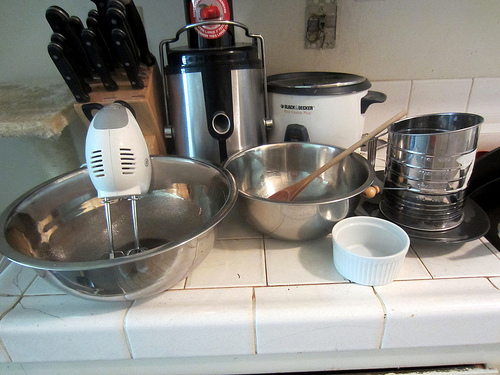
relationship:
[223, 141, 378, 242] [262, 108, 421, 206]
bowl with spoon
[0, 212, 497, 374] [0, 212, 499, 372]
tiles on counter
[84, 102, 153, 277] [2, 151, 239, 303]
hand mixer in bowl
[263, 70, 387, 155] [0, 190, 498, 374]
crock pot on counter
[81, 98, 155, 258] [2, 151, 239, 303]
hand mixer in bowl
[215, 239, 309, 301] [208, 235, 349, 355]
grout between tiles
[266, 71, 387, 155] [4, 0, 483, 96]
crock pot against wall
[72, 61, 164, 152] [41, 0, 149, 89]
brick with knives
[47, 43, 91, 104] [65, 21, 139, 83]
knife with handles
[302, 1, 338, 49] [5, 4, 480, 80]
socket on wall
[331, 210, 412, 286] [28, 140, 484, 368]
bowl on counter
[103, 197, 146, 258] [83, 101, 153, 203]
blades on mixer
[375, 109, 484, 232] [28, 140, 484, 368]
sifter on counter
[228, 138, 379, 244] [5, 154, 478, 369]
bowl on counter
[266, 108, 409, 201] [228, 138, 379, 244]
spoon in bowl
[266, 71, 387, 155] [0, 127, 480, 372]
crock pot on counter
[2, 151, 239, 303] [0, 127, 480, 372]
bowl on counter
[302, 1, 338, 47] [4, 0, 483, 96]
socket on wall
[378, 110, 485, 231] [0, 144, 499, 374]
sifter on counter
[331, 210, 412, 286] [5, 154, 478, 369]
bowl on counter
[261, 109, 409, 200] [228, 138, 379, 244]
spoon lying in bowl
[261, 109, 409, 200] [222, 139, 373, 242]
spoon lying in bowl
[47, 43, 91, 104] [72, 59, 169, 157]
knife placed into block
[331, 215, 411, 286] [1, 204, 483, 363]
bowl sitting on top of counter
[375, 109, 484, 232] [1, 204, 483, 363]
sifter sitting on top of counter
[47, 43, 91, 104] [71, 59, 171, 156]
knife placed on counter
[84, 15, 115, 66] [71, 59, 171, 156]
knife placed on counter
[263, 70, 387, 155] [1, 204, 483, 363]
crock pot sitting on top of counter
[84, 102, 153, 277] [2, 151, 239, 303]
hand mixer placed inside bowl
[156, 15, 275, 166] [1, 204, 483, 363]
appliance sitting on top of counter